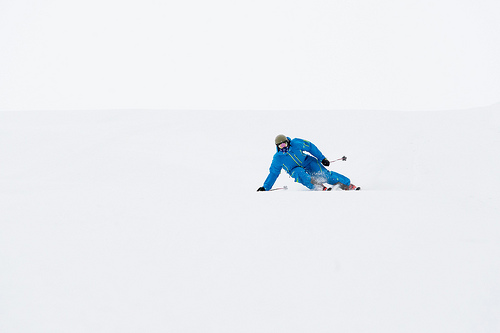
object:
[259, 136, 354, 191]
jacket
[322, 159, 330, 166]
glove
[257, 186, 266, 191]
glove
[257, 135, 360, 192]
skier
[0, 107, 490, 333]
slope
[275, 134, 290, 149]
helmet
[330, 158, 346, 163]
pole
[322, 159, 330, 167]
hand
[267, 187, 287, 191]
pole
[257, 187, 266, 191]
hand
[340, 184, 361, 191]
skates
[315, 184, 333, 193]
skates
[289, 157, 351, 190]
pants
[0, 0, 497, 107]
sky